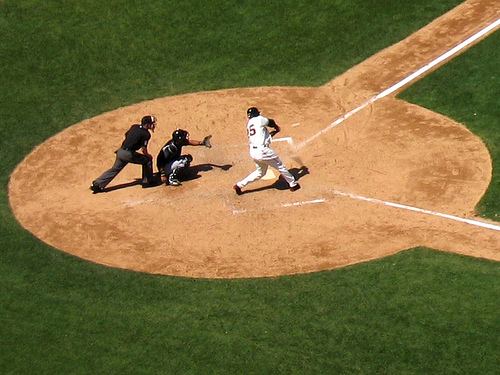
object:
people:
[230, 105, 300, 196]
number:
[246, 124, 257, 137]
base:
[259, 165, 279, 181]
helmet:
[243, 105, 262, 119]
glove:
[198, 134, 213, 149]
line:
[329, 190, 499, 232]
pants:
[235, 157, 298, 189]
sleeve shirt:
[121, 123, 153, 151]